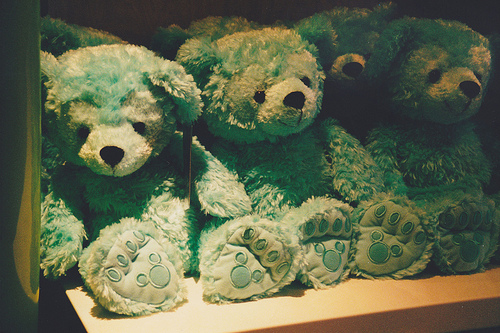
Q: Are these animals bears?
A: Yes, all the animals are bears.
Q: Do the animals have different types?
A: No, all the animals are bears.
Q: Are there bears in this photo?
A: Yes, there is a bear.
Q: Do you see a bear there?
A: Yes, there is a bear.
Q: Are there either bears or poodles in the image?
A: Yes, there is a bear.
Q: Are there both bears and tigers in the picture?
A: No, there is a bear but no tigers.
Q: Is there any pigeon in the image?
A: No, there are no pigeons.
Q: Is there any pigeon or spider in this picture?
A: No, there are no pigeons or spiders.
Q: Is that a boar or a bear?
A: That is a bear.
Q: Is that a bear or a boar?
A: That is a bear.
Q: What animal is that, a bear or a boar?
A: That is a bear.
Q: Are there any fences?
A: No, there are no fences.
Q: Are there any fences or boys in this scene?
A: No, there are no fences or boys.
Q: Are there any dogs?
A: No, there are no dogs.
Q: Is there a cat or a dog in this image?
A: No, there are no dogs or cats.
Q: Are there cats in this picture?
A: No, there are no cats.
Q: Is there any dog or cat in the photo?
A: No, there are no cats or dogs.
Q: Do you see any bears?
A: Yes, there is a bear.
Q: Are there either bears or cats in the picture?
A: Yes, there is a bear.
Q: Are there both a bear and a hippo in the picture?
A: No, there is a bear but no hippoes.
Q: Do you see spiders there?
A: No, there are no spiders.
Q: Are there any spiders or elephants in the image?
A: No, there are no spiders or elephants.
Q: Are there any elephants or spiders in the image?
A: No, there are no spiders or elephants.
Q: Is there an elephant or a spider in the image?
A: No, there are no spiders or elephants.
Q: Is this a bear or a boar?
A: This is a bear.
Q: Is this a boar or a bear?
A: This is a bear.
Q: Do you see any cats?
A: No, there are no cats.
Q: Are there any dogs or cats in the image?
A: No, there are no cats or dogs.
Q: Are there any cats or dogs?
A: No, there are no cats or dogs.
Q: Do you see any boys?
A: No, there are no boys.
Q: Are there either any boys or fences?
A: No, there are no boys or fences.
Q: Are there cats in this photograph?
A: No, there are no cats.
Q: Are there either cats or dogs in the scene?
A: No, there are no cats or dogs.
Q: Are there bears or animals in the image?
A: Yes, there is a bear.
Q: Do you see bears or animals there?
A: Yes, there is a bear.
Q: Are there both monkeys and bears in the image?
A: No, there is a bear but no monkeys.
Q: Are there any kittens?
A: No, there are no kittens.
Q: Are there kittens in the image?
A: No, there are no kittens.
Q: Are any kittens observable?
A: No, there are no kittens.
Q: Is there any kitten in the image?
A: No, there are no kittens.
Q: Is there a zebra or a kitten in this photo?
A: No, there are no kittens or zebras.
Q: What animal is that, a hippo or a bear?
A: That is a bear.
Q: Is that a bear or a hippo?
A: That is a bear.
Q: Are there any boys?
A: No, there are no boys.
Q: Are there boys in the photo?
A: No, there are no boys.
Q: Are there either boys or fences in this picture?
A: No, there are no boys or fences.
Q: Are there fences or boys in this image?
A: No, there are no boys or fences.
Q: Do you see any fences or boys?
A: No, there are no boys or fences.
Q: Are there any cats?
A: No, there are no cats.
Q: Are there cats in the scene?
A: No, there are no cats.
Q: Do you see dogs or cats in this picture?
A: No, there are no cats or dogs.